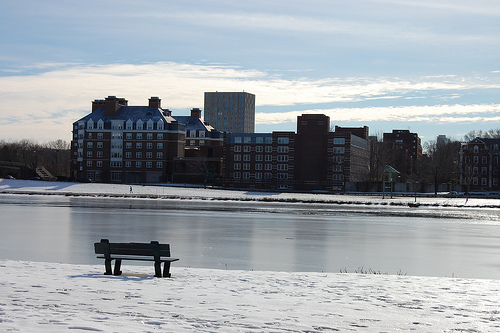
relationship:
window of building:
[154, 117, 165, 137] [61, 93, 186, 180]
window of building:
[276, 135, 290, 144] [221, 129, 371, 190]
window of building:
[470, 143, 480, 159] [454, 133, 496, 198]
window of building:
[125, 115, 135, 129] [68, 89, 223, 183]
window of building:
[232, 138, 240, 145] [220, 105, 371, 197]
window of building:
[480, 174, 491, 185] [439, 127, 499, 206]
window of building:
[123, 159, 133, 169] [68, 89, 223, 183]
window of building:
[261, 161, 272, 172] [220, 105, 371, 197]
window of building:
[480, 167, 493, 181] [452, 132, 497, 201]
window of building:
[465, 153, 471, 165] [446, 130, 497, 207]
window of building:
[333, 144, 345, 153] [223, 109, 422, 201]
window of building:
[111, 157, 123, 168] [68, 89, 223, 183]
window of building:
[97, 120, 106, 131] [68, 89, 223, 183]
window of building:
[254, 133, 265, 143] [223, 109, 422, 201]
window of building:
[469, 152, 481, 166] [432, 133, 496, 197]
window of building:
[467, 162, 478, 172] [442, 130, 495, 199]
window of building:
[277, 152, 290, 162] [223, 109, 422, 201]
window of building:
[197, 126, 208, 137] [68, 89, 223, 183]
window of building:
[74, 146, 85, 158] [68, 89, 223, 183]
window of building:
[254, 160, 264, 172] [223, 109, 422, 201]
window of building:
[482, 164, 493, 176] [425, 121, 494, 202]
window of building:
[480, 166, 489, 176] [68, 89, 223, 183]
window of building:
[232, 161, 239, 171] [223, 109, 422, 201]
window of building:
[111, 129, 124, 140] [429, 130, 497, 206]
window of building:
[143, 138, 154, 151] [68, 89, 223, 183]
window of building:
[273, 160, 291, 171] [223, 109, 422, 201]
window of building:
[464, 165, 470, 177] [436, 129, 496, 207]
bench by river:
[93, 239, 178, 277] [6, 200, 496, 290]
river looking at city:
[6, 200, 496, 290] [6, 65, 498, 219]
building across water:
[68, 89, 223, 183] [1, 199, 498, 284]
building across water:
[223, 109, 422, 201] [1, 199, 498, 284]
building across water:
[432, 133, 496, 197] [1, 199, 498, 284]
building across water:
[68, 89, 223, 183] [3, 190, 495, 276]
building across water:
[223, 109, 422, 201] [3, 190, 495, 276]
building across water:
[432, 133, 496, 197] [3, 190, 495, 276]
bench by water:
[93, 239, 178, 277] [3, 190, 495, 276]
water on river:
[300, 220, 490, 260] [16, 178, 493, 279]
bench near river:
[93, 239, 178, 277] [1, 195, 496, 275]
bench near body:
[91, 233, 179, 279] [5, 195, 493, 283]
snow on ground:
[374, 293, 468, 312] [3, 264, 498, 331]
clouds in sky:
[266, 73, 493, 105] [2, 1, 497, 115]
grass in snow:
[331, 271, 411, 275] [199, 267, 356, 315]